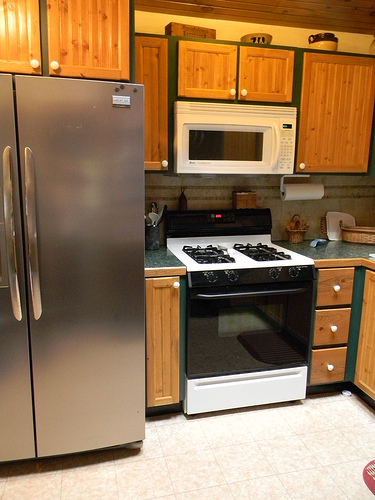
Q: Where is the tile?
A: On the floor.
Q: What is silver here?
A: The icebox.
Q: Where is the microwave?
A: Over the stove.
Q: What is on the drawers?
A: Knobs.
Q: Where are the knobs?
A: On the drawers.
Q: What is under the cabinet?
A: Paper towels.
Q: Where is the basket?
A: On the counter.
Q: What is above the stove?
A: Microwave.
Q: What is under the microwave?
A: Stove.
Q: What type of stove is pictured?
A: Gas.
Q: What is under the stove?
A: Oven.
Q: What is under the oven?
A: Drawer.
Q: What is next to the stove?
A: Refrigerator.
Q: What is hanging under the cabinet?
A: Paper Towels.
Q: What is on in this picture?
A: Oven Clock.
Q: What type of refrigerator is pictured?
A: Stainless steel.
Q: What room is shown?
A: Kitchen.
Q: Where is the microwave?
A: Above the stove.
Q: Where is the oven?
A: Between cupboards.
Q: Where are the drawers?
A: Under the counter.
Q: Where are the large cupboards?
A: By the microwave.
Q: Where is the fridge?
A: On the left.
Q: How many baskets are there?
A: 2.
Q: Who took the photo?
A: The photographer.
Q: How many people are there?
A: None.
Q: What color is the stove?
A: White and black.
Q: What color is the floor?
A: White.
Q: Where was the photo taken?
A: A kitchen.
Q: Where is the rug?
A: In the lower right hand corner.